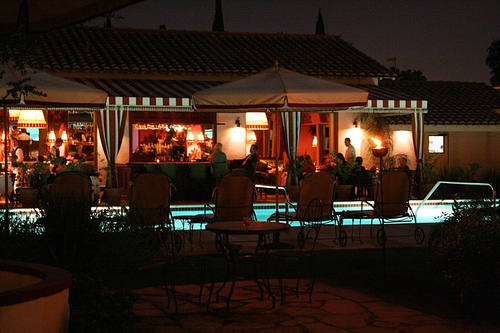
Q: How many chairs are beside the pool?
A: Five.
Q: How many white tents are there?
A: Two.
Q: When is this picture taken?
A: At night.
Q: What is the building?
A: A restaurant.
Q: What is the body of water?
A: Pool.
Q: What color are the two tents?
A: White.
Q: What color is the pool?
A: Blue.